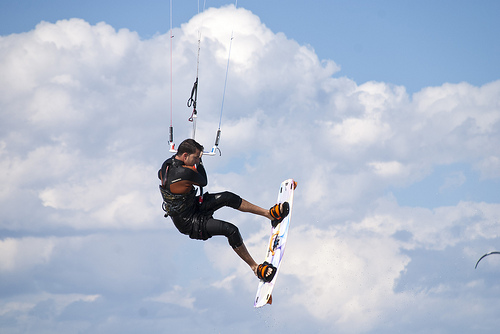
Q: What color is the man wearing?
A: Black and orange.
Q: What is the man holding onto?
A: A rope.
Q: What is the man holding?
A: A bar with ropes.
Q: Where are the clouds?
A: Sky.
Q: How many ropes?
A: Three.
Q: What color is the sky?
A: Blue.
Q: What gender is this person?
A: Male.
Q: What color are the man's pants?
A: Black.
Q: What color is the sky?
A: Blue.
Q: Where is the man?
A: Air.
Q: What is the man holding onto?
A: Bar.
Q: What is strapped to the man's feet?
A: Board.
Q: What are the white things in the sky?
A: Clouds.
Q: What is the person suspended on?
A: Ropes.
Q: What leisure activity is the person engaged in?
A: Kitesurfing.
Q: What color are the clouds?
A: White.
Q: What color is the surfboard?
A: White.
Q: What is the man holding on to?
A: Harness.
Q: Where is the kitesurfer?
A: Suspended in midair.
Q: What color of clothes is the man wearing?
A: Black.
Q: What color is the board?
A: White.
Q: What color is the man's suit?
A: Black.